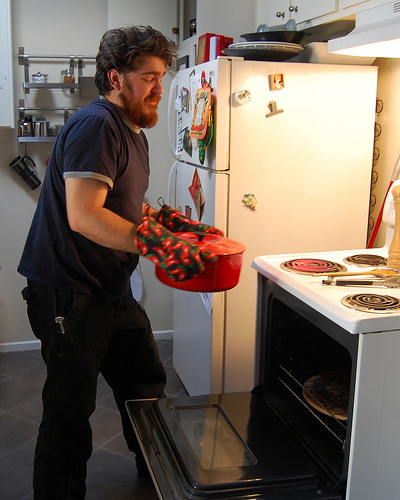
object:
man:
[17, 24, 167, 500]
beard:
[118, 90, 161, 128]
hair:
[96, 25, 172, 94]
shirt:
[18, 104, 150, 293]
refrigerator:
[174, 63, 382, 401]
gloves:
[135, 220, 206, 284]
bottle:
[8, 155, 42, 189]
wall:
[0, 0, 170, 334]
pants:
[24, 277, 164, 500]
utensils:
[321, 280, 398, 286]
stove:
[254, 252, 399, 335]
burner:
[281, 258, 346, 277]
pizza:
[302, 373, 349, 420]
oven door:
[125, 394, 348, 500]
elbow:
[67, 212, 85, 237]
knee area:
[138, 356, 167, 398]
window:
[177, 404, 258, 469]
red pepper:
[172, 240, 183, 250]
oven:
[126, 245, 400, 490]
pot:
[156, 232, 246, 292]